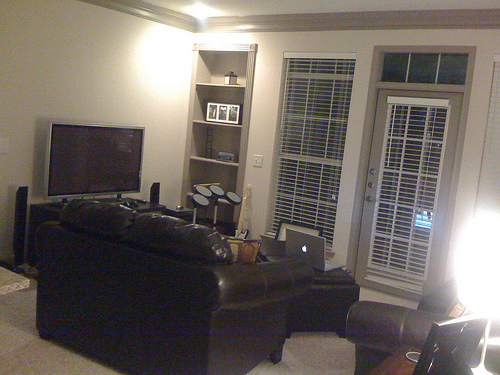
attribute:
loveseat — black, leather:
[32, 200, 315, 374]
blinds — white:
[271, 52, 356, 265]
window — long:
[260, 50, 358, 266]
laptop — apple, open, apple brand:
[285, 227, 345, 274]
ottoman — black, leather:
[255, 241, 359, 339]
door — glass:
[344, 44, 478, 302]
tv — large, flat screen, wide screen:
[45, 119, 148, 196]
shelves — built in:
[182, 40, 258, 233]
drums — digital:
[189, 185, 244, 230]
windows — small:
[380, 52, 470, 85]